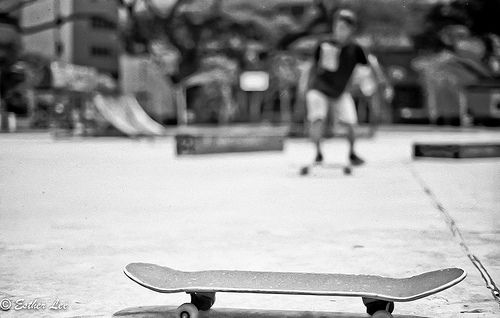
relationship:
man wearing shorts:
[306, 17, 386, 170] [306, 81, 381, 141]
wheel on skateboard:
[171, 296, 198, 315] [120, 247, 475, 314]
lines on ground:
[407, 165, 499, 307] [152, 196, 412, 259]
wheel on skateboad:
[171, 304, 201, 318] [96, 233, 477, 316]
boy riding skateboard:
[295, 5, 396, 164] [118, 261, 468, 315]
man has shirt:
[306, 17, 386, 170] [306, 36, 371, 99]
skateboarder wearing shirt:
[267, 7, 445, 235] [306, 36, 371, 99]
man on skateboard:
[306, 17, 386, 170] [303, 162, 352, 174]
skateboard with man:
[295, 157, 361, 178] [313, 7, 376, 186]